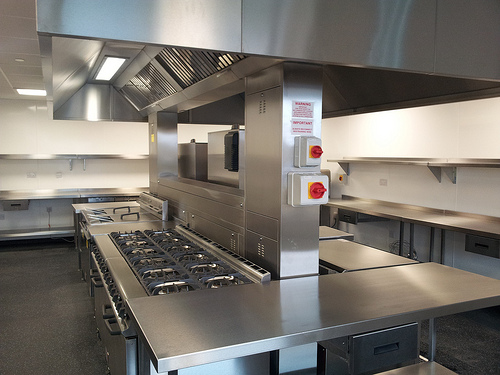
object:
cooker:
[144, 226, 185, 240]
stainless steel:
[201, 257, 411, 349]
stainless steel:
[51, 62, 188, 123]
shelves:
[324, 155, 499, 168]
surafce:
[294, 232, 313, 264]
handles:
[120, 211, 141, 220]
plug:
[378, 178, 389, 188]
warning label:
[290, 97, 314, 136]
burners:
[183, 259, 235, 279]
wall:
[147, 61, 283, 279]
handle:
[100, 300, 115, 321]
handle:
[100, 313, 125, 336]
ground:
[451, 319, 498, 365]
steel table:
[125, 260, 500, 373]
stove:
[163, 241, 202, 256]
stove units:
[104, 224, 254, 299]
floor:
[7, 250, 85, 372]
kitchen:
[2, 2, 497, 373]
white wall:
[393, 172, 420, 200]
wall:
[0, 162, 152, 186]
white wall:
[467, 172, 497, 210]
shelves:
[1, 151, 150, 161]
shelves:
[1, 186, 154, 203]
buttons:
[310, 145, 325, 159]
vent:
[115, 53, 187, 112]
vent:
[154, 43, 258, 93]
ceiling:
[0, 0, 498, 115]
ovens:
[89, 267, 148, 373]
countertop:
[126, 257, 498, 365]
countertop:
[340, 245, 364, 265]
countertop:
[329, 190, 500, 234]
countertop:
[1, 187, 148, 200]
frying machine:
[70, 189, 169, 226]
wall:
[357, 167, 424, 198]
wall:
[283, 75, 323, 135]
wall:
[0, 103, 148, 153]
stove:
[129, 252, 175, 273]